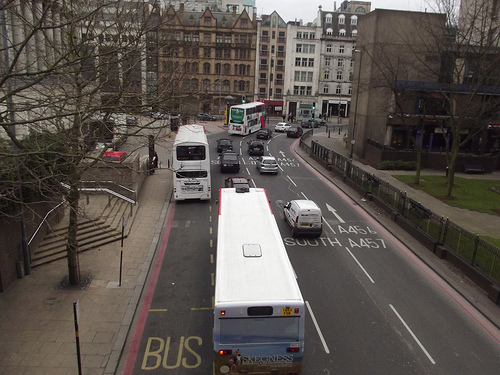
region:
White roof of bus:
[216, 186, 307, 307]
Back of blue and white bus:
[213, 306, 309, 371]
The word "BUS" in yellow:
[138, 332, 204, 371]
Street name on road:
[279, 232, 394, 255]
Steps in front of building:
[27, 187, 140, 267]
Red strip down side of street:
[114, 191, 180, 374]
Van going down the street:
[283, 198, 325, 232]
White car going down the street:
[271, 121, 292, 132]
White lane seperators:
[264, 121, 441, 369]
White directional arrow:
[321, 198, 349, 228]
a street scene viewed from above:
[14, 3, 498, 371]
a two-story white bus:
[171, 123, 216, 220]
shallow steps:
[13, 177, 141, 277]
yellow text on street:
[137, 313, 208, 374]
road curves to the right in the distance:
[172, 85, 354, 222]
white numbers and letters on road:
[281, 197, 396, 257]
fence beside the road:
[302, 138, 499, 303]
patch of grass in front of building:
[350, 8, 499, 225]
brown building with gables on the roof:
[155, 3, 260, 120]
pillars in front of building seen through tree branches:
[4, 0, 94, 158]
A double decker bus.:
[171, 123, 216, 203]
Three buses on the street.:
[144, 91, 312, 365]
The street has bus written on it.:
[129, 324, 209, 374]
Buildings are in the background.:
[67, 0, 356, 127]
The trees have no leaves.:
[15, 7, 172, 286]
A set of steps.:
[86, 195, 137, 247]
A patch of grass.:
[401, 165, 497, 225]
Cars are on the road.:
[214, 122, 311, 182]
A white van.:
[282, 193, 343, 253]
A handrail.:
[74, 170, 150, 220]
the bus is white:
[166, 118, 221, 204]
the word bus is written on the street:
[119, 323, 220, 373]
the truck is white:
[281, 193, 324, 243]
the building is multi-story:
[157, 2, 271, 115]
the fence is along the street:
[350, 133, 489, 298]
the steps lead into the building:
[26, 215, 139, 275]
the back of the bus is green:
[228, 99, 248, 128]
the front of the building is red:
[262, 87, 289, 119]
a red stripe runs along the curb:
[113, 202, 168, 371]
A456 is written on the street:
[334, 215, 382, 235]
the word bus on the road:
[135, 334, 208, 368]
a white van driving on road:
[288, 192, 328, 242]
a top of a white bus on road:
[209, 184, 299, 374]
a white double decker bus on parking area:
[168, 119, 215, 209]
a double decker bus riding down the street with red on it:
[223, 97, 271, 135]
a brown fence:
[362, 140, 497, 280]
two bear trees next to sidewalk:
[413, 14, 465, 195]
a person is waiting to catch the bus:
[121, 105, 221, 211]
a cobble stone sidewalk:
[4, 240, 165, 374]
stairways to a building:
[23, 195, 138, 267]